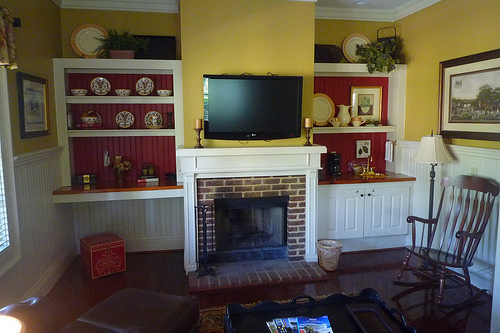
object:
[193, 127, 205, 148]
candle stick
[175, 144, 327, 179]
mantle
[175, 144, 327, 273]
mantlepiece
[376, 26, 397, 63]
basket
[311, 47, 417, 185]
shelf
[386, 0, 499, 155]
wall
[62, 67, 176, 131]
dishes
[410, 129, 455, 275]
floor lamp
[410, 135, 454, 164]
white shade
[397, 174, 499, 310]
rocking chair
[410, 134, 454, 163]
ground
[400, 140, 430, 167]
ground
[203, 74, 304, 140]
television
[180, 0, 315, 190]
wall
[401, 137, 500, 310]
wall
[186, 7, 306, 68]
yellow wall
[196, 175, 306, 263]
fire place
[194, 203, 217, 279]
tools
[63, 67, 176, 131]
display plates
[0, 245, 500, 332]
floor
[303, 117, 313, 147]
candle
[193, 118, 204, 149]
candle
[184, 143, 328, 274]
mantlepiece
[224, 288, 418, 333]
coffee table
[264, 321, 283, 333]
magazines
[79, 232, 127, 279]
gold box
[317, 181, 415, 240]
cabinet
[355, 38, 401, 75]
plant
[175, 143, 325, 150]
mantle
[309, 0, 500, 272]
wall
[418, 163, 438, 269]
base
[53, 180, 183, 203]
shelf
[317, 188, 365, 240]
door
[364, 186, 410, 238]
door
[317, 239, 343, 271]
waste basket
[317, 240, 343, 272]
liner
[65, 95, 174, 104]
shelf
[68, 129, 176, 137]
shelf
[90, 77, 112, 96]
display plate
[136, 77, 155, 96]
display plate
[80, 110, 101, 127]
display plate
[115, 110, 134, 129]
display plate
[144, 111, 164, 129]
display plate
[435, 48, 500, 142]
painting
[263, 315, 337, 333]
group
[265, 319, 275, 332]
magazine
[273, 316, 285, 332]
magazine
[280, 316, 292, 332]
magazine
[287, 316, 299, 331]
magazine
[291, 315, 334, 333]
magazine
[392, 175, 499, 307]
chair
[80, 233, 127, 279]
box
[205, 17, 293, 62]
wall